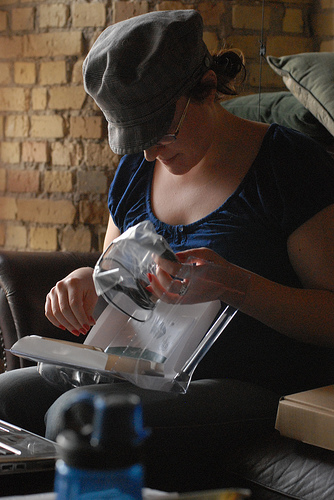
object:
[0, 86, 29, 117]
brick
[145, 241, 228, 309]
hand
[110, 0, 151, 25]
brick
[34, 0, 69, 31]
brick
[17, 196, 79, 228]
brick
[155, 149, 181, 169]
mouth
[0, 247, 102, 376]
arm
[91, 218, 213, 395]
package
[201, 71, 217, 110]
ear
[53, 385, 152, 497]
bottle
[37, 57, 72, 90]
brick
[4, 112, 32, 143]
brick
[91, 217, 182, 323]
plastic sack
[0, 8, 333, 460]
woman unpacking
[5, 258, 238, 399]
electronic device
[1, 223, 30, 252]
brick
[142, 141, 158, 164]
nose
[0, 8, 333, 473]
woman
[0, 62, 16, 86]
brick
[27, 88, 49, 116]
brick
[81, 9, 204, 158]
cap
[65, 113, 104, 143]
brick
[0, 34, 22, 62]
brick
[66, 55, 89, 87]
brick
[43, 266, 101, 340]
hand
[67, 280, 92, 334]
fingers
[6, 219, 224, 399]
plastic box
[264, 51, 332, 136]
pillows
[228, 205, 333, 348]
arm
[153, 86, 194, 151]
glasses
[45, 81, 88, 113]
brick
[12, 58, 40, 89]
brick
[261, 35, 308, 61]
brick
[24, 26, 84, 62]
brick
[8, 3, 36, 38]
brick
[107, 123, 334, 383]
blouse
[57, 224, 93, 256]
brick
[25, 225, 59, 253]
brick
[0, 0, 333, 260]
wall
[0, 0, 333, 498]
building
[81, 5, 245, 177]
head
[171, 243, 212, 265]
thumb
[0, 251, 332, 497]
sofa